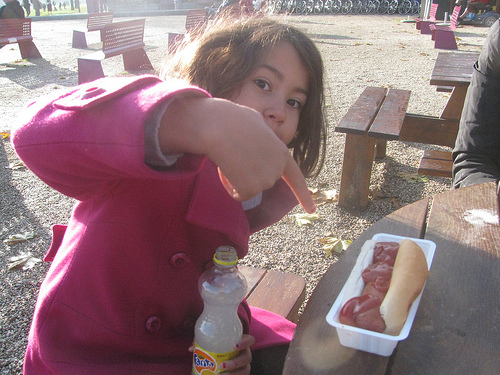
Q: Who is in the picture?
A: A girl.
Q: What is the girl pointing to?
A: Hot dog.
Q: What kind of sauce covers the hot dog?
A: Ketchup.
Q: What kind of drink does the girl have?
A: Fanta.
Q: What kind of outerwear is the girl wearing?
A: Pink coat.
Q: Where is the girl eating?
A: Picnic table.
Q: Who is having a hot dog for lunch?
A: The young girl.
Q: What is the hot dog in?
A: White box.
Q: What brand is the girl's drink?
A: Fanta.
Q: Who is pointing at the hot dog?
A: The girl in the pink coat.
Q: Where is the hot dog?
A: In the white tray.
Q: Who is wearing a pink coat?
A: The girl pointing at a hot dog.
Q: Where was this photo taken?
A: Outside at a table.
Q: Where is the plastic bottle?
A: In the girl's hand.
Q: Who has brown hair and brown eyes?
A: The girl wearing the pink coat.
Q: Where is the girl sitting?
A: At an outdoor table.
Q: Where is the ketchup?
A: On the hot dog.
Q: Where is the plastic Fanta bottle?
A: In the girl's left hand.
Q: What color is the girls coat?
A: Pink.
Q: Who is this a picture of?
A: A little girl.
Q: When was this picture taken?
A: Daytime.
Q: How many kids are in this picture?
A: One.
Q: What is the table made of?
A: Wood.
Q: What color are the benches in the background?
A: Red.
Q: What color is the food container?
A: White.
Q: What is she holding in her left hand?
A: A drink.